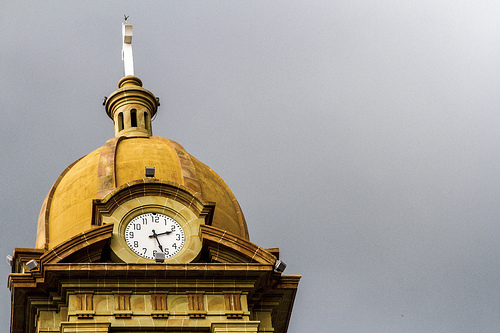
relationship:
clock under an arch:
[123, 206, 184, 258] [85, 177, 216, 217]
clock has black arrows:
[123, 206, 184, 258] [146, 229, 174, 250]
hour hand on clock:
[148, 229, 171, 238] [123, 209, 185, 261]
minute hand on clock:
[151, 230, 165, 253] [123, 209, 185, 261]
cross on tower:
[118, 22, 138, 72] [4, 18, 303, 331]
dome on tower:
[32, 135, 250, 250] [4, 18, 303, 331]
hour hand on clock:
[148, 228, 174, 238] [123, 209, 185, 261]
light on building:
[272, 257, 288, 274] [4, 23, 302, 332]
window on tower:
[116, 112, 125, 131] [4, 18, 303, 331]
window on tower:
[128, 107, 136, 127] [4, 18, 303, 331]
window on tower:
[143, 110, 150, 130] [4, 18, 303, 331]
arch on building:
[23, 225, 280, 274] [4, 14, 302, 333]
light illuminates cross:
[20, 255, 40, 276] [118, 22, 136, 78]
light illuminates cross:
[272, 261, 285, 274] [118, 22, 136, 78]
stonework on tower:
[36, 286, 263, 331] [4, 18, 303, 331]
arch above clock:
[91, 178, 216, 227] [123, 211, 183, 257]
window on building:
[114, 112, 126, 131] [4, 14, 302, 333]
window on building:
[128, 107, 140, 129] [4, 14, 302, 333]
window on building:
[143, 110, 153, 130] [4, 14, 302, 333]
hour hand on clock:
[148, 228, 174, 238] [125, 213, 185, 257]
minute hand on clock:
[151, 230, 165, 252] [125, 213, 185, 257]